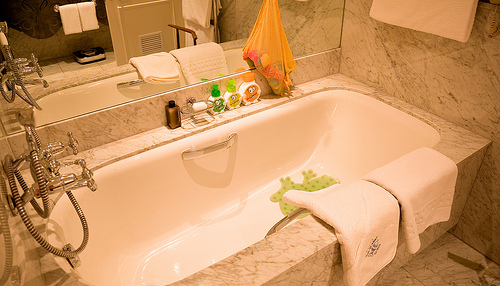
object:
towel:
[282, 177, 401, 285]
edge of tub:
[167, 129, 494, 286]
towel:
[361, 144, 459, 257]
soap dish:
[191, 101, 208, 111]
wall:
[0, 0, 500, 266]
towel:
[368, 0, 481, 44]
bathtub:
[0, 72, 492, 286]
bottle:
[165, 98, 182, 129]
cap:
[168, 99, 176, 108]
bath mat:
[271, 170, 337, 216]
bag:
[240, 0, 297, 96]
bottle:
[224, 80, 242, 109]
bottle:
[208, 83, 226, 114]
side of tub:
[6, 70, 343, 201]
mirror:
[0, 0, 344, 139]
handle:
[183, 130, 237, 166]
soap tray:
[178, 97, 213, 118]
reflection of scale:
[69, 44, 106, 65]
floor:
[381, 232, 499, 285]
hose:
[2, 134, 90, 262]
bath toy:
[257, 50, 270, 68]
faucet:
[49, 161, 101, 192]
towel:
[127, 48, 180, 85]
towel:
[170, 38, 229, 88]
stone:
[0, 0, 500, 285]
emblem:
[366, 235, 384, 258]